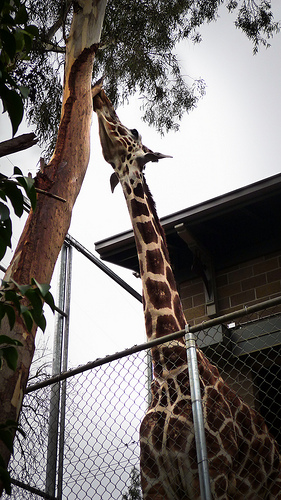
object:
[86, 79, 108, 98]
branch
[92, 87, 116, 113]
giraffe's mouth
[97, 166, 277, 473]
facility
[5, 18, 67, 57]
tree branches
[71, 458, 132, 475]
power lines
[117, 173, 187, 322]
neck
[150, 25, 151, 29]
leaves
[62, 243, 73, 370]
poles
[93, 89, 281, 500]
giraffe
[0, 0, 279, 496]
tree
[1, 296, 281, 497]
fence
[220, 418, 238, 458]
spots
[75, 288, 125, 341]
sky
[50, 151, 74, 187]
bark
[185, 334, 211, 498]
post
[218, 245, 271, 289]
wall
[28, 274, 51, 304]
leaves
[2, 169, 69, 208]
branches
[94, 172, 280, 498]
building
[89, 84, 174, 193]
head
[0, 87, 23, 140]
leaves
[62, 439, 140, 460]
powerlines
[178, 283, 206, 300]
bricks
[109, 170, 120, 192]
ear